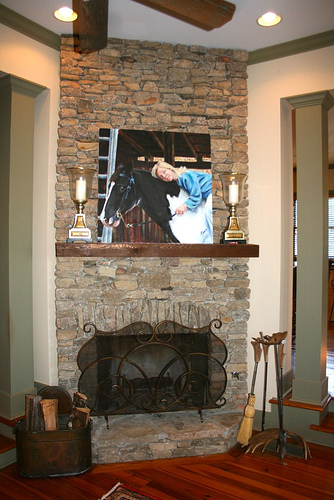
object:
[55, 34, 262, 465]
fireplace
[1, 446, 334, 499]
floor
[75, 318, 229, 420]
cover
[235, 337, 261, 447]
broom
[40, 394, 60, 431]
logs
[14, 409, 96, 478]
container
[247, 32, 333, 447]
wall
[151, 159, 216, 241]
woman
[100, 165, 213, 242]
horse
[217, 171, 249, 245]
candleholder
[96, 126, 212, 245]
picture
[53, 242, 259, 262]
mantle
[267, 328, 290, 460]
tools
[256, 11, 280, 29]
light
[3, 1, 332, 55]
ceiling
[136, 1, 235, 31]
blade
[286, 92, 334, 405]
column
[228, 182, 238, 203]
candle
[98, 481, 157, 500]
rug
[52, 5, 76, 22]
light